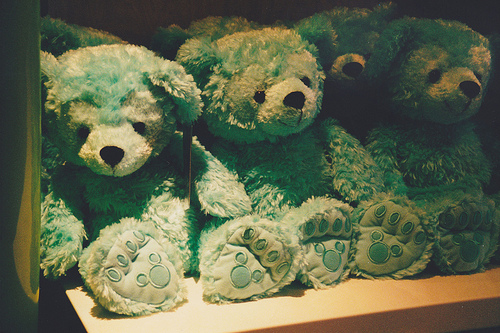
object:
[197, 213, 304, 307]
foot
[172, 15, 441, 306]
bear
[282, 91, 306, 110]
nose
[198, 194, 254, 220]
paw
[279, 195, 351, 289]
foot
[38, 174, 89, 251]
arm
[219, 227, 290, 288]
paw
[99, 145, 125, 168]
nose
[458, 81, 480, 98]
nose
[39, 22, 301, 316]
bear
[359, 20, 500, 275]
bear